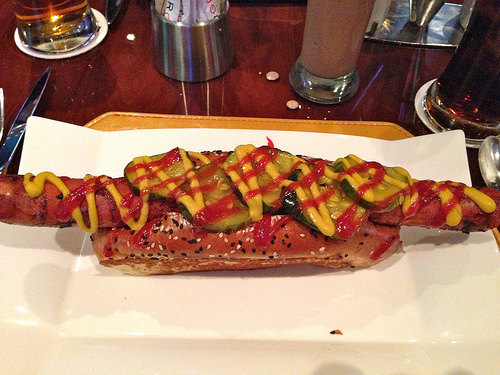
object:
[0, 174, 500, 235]
hot dog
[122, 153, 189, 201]
pickle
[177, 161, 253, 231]
pickle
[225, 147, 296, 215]
pickle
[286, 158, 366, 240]
pickle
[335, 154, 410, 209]
pickle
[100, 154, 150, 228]
ketchup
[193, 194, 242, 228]
ketchup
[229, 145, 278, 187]
ketchup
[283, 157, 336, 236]
ketchup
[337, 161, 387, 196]
ketchup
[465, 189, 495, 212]
mustard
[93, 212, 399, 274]
bun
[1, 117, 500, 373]
plate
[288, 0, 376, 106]
glass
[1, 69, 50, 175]
knife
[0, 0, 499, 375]
table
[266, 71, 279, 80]
pill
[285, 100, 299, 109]
pill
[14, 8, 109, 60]
coaster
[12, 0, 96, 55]
drink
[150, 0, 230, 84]
container